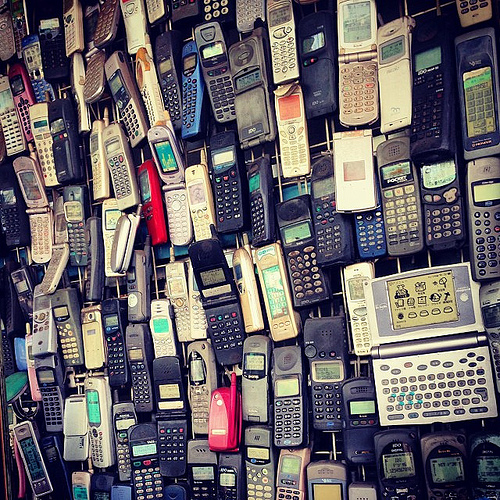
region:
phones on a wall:
[84, 368, 123, 462]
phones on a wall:
[147, 409, 213, 464]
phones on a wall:
[208, 374, 245, 447]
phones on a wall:
[256, 355, 312, 455]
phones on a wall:
[274, 210, 321, 286]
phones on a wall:
[190, 160, 257, 233]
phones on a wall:
[121, 143, 174, 264]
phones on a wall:
[133, 107, 185, 235]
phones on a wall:
[93, 107, 145, 219]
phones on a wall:
[18, 92, 60, 197]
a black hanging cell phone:
[275, 196, 328, 309]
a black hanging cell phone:
[305, 155, 350, 267]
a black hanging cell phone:
[413, 138, 467, 253]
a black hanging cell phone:
[302, 318, 344, 433]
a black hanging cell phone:
[343, 378, 376, 465]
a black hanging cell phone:
[373, 430, 425, 499]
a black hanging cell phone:
[421, 429, 467, 497]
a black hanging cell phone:
[216, 453, 242, 499]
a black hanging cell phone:
[148, 354, 188, 476]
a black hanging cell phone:
[125, 421, 163, 498]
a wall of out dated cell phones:
[5, 9, 491, 498]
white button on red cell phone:
[215, 399, 223, 409]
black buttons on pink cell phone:
[272, 486, 306, 498]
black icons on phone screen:
[387, 282, 445, 318]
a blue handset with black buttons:
[179, 41, 206, 143]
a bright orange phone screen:
[278, 94, 298, 119]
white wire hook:
[417, 7, 439, 17]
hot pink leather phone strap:
[9, 446, 29, 498]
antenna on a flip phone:
[135, 202, 151, 216]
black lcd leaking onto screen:
[296, 36, 315, 51]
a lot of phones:
[1, 0, 498, 498]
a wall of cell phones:
[1, 2, 498, 499]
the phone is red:
[208, 372, 245, 448]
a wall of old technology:
[0, 0, 496, 496]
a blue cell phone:
[183, 40, 200, 132]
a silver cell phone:
[164, 259, 189, 337]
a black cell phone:
[308, 315, 349, 432]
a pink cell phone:
[23, 323, 43, 399]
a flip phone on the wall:
[16, 154, 53, 266]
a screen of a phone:
[275, 375, 296, 395]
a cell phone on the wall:
[12, 425, 53, 496]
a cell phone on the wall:
[128, 424, 159, 496]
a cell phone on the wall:
[207, 372, 234, 444]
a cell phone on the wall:
[273, 345, 303, 448]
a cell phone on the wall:
[303, 316, 345, 426]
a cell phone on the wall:
[338, 387, 380, 464]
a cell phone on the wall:
[276, 199, 326, 304]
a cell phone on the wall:
[184, 157, 212, 239]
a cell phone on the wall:
[107, 204, 142, 271]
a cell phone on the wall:
[61, 184, 85, 266]